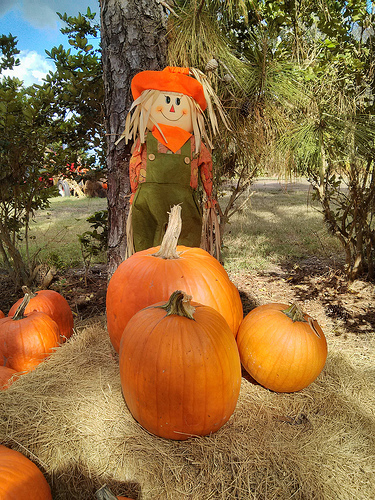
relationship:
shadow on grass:
[221, 182, 342, 270] [6, 184, 362, 266]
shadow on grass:
[44, 464, 144, 499] [1, 324, 374, 498]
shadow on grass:
[122, 360, 372, 500] [1, 324, 374, 498]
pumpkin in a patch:
[120, 293, 241, 439] [0, 179, 374, 498]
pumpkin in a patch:
[106, 205, 243, 357] [0, 179, 374, 498]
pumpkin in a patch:
[238, 305, 329, 395] [0, 179, 374, 498]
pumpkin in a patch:
[0, 296, 61, 372] [0, 179, 374, 498]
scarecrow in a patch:
[125, 66, 219, 249] [0, 179, 374, 498]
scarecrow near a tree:
[125, 66, 219, 249] [95, 1, 177, 279]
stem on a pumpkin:
[156, 204, 183, 260] [106, 205, 243, 357]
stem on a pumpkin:
[158, 293, 199, 321] [120, 293, 241, 439]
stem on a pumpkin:
[17, 294, 29, 320] [0, 296, 61, 372]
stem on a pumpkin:
[285, 302, 306, 322] [238, 305, 329, 395]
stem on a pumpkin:
[24, 285, 35, 297] [0, 291, 61, 372]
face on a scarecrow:
[148, 89, 194, 136] [125, 66, 219, 249]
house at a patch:
[35, 160, 109, 201] [0, 179, 374, 498]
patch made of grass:
[0, 179, 374, 498] [6, 184, 362, 266]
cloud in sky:
[2, 52, 57, 93] [1, 0, 372, 102]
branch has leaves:
[302, 140, 349, 243] [334, 178, 340, 188]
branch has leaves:
[302, 140, 349, 243] [333, 178, 341, 186]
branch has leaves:
[79, 37, 86, 48] [87, 8, 98, 20]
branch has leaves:
[79, 37, 86, 48] [54, 11, 70, 21]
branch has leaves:
[79, 37, 86, 48] [44, 48, 53, 55]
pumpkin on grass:
[0, 291, 61, 372] [1, 324, 374, 498]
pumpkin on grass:
[238, 305, 329, 395] [1, 324, 374, 498]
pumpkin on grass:
[0, 296, 61, 372] [1, 324, 374, 498]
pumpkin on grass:
[106, 205, 243, 357] [1, 324, 374, 498]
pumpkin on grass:
[120, 293, 241, 439] [1, 324, 374, 498]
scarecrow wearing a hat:
[125, 66, 219, 249] [130, 67, 213, 110]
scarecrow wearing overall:
[125, 66, 219, 249] [130, 128, 206, 248]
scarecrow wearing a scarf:
[125, 66, 219, 249] [150, 125, 194, 153]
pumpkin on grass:
[0, 442, 55, 499] [1, 324, 374, 498]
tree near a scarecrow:
[95, 1, 177, 279] [125, 66, 219, 249]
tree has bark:
[95, 1, 177, 279] [97, 0, 195, 276]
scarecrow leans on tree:
[125, 66, 219, 249] [95, 1, 177, 279]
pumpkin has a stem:
[106, 205, 243, 357] [156, 204, 183, 260]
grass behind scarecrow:
[6, 184, 362, 266] [125, 66, 219, 249]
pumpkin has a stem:
[120, 293, 241, 439] [158, 293, 199, 321]